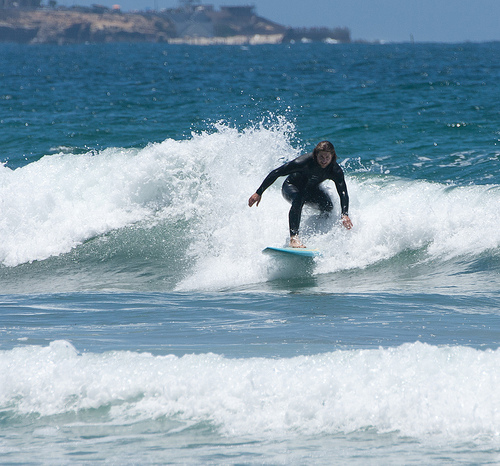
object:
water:
[0, 272, 500, 466]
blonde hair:
[313, 140, 336, 160]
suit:
[258, 154, 349, 237]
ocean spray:
[207, 87, 306, 222]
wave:
[0, 339, 500, 439]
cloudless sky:
[261, 0, 499, 46]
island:
[2, 5, 348, 49]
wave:
[205, 127, 268, 176]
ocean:
[0, 47, 500, 466]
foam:
[0, 334, 497, 444]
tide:
[2, 123, 500, 292]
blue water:
[5, 39, 498, 170]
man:
[249, 140, 354, 248]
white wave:
[3, 110, 498, 286]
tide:
[1, 333, 499, 464]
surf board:
[262, 247, 320, 257]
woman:
[248, 140, 353, 248]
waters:
[72, 158, 220, 310]